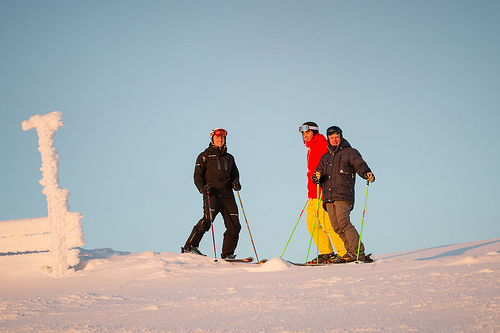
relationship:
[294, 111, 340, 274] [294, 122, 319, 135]
skier wears goggles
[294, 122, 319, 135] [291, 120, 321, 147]
goggles on head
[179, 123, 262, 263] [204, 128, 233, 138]
skier wears goggles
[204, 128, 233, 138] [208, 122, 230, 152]
goggles on head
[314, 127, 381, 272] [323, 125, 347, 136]
skier wears goggles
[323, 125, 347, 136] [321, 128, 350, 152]
goggles on head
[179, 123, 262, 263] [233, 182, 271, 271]
skier holds pole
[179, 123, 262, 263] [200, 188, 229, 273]
skier holds pole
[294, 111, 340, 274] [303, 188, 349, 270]
skier wears pants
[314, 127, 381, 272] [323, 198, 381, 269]
skier wears pants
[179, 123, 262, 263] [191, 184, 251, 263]
skier wears pants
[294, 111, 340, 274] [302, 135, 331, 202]
skier wears coat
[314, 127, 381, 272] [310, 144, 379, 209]
skier wears coat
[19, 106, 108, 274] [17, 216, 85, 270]
sculputure from ice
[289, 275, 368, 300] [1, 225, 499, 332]
tracks on snow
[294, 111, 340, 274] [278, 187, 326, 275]
skier holds poles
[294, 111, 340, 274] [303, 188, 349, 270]
skier wearing pants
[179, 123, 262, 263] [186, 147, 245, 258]
skier wearing black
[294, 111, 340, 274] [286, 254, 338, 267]
skier has skies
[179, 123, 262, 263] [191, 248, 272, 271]
skier has skies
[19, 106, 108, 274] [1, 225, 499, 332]
sculputure made of snow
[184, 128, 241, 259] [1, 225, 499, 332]
skier on snow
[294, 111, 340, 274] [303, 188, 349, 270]
skier has pants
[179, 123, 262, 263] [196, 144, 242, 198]
skier wears jacket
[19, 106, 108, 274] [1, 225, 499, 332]
sculputure of snow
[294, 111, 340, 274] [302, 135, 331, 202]
skier wearing coat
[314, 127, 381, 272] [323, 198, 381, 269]
skier wearing pants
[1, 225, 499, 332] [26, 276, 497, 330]
snow on ground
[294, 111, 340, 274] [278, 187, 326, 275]
skier holding poles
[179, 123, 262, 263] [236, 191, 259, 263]
skier holding pole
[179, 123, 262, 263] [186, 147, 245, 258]
skier wears black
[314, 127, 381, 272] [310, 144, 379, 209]
skier wearing coat